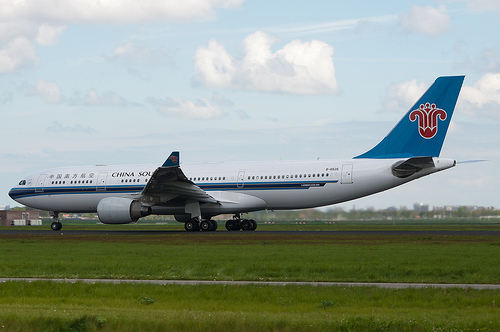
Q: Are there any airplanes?
A: Yes, there is an airplane.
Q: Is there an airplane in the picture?
A: Yes, there is an airplane.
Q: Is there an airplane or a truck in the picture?
A: Yes, there is an airplane.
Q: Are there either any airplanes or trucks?
A: Yes, there is an airplane.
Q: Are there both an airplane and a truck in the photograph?
A: No, there is an airplane but no trucks.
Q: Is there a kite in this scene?
A: No, there are no kites.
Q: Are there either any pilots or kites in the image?
A: No, there are no kites or pilots.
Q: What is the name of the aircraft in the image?
A: The aircraft is an airplane.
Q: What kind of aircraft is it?
A: The aircraft is an airplane.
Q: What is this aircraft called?
A: This is an airplane.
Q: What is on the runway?
A: The plane is on the runway.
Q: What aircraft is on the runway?
A: The aircraft is an airplane.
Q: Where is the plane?
A: The plane is on the runway.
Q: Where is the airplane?
A: The plane is on the runway.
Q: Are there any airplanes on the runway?
A: Yes, there is an airplane on the runway.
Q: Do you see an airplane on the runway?
A: Yes, there is an airplane on the runway.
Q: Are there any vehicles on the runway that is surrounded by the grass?
A: No, there is an airplane on the runway.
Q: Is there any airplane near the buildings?
A: Yes, there is an airplane near the buildings.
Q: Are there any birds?
A: No, there are no birds.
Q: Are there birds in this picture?
A: No, there are no birds.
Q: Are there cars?
A: No, there are no cars.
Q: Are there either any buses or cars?
A: No, there are no cars or buses.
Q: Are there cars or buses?
A: No, there are no cars or buses.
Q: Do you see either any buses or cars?
A: No, there are no cars or buses.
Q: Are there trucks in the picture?
A: No, there are no trucks.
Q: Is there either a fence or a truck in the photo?
A: No, there are no trucks or fences.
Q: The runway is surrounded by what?
A: The runway is surrounded by the grass.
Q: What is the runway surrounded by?
A: The runway is surrounded by the grass.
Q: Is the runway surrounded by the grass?
A: Yes, the runway is surrounded by the grass.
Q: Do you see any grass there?
A: Yes, there is grass.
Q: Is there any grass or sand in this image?
A: Yes, there is grass.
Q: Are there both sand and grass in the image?
A: No, there is grass but no sand.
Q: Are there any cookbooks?
A: No, there are no cookbooks.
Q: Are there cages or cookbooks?
A: No, there are no cookbooks or cages.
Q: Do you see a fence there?
A: No, there are no fences.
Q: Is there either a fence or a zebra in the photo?
A: No, there are no fences or zebras.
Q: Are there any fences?
A: No, there are no fences.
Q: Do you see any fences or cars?
A: No, there are no fences or cars.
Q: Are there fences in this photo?
A: No, there are no fences.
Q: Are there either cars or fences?
A: No, there are no fences or cars.